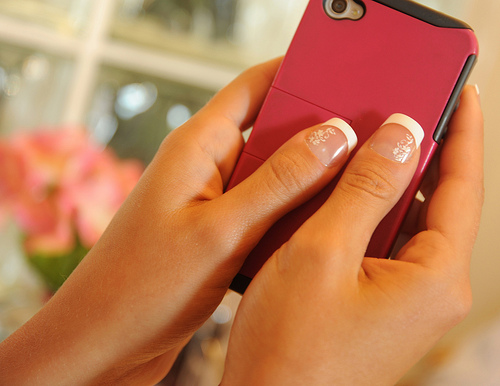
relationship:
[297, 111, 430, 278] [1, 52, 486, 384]
thumb of a person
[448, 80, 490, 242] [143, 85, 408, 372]
finger of a person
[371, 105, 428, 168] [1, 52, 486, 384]
nail of a person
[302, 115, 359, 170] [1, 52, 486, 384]
nail of a person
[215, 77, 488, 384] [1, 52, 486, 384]
hand of a person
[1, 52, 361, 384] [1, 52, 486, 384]
hand of a person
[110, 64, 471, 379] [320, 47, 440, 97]
person holding phone